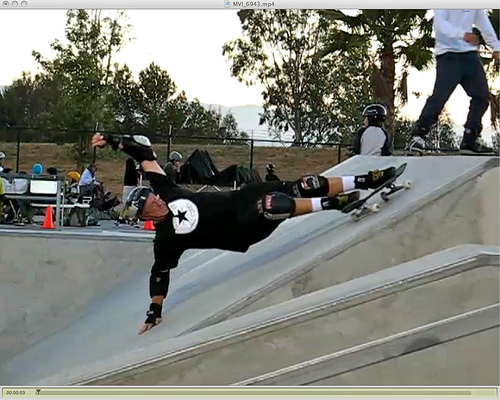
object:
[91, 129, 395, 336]
skater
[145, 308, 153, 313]
wristguard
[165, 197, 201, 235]
logo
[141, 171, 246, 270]
shirt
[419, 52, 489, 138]
pants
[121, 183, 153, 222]
helmet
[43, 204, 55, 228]
cone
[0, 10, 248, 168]
tree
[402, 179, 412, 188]
wheel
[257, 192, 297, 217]
kneepad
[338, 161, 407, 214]
board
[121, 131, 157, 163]
elbowpad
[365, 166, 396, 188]
shoe